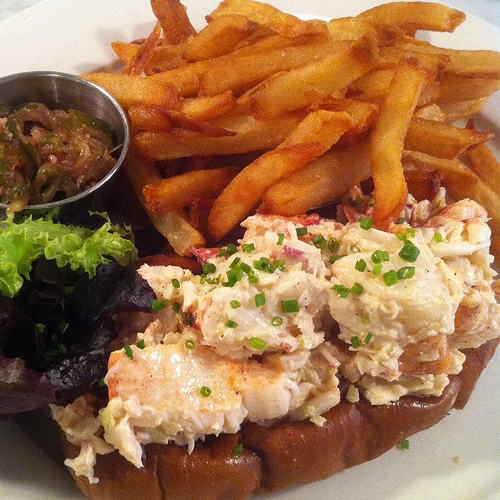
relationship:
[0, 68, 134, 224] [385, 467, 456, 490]
container on plate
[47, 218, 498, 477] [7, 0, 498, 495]
onions on plate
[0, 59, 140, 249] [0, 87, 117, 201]
container of peppers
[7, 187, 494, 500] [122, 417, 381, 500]
food on bun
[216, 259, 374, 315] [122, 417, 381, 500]
toppings on bun